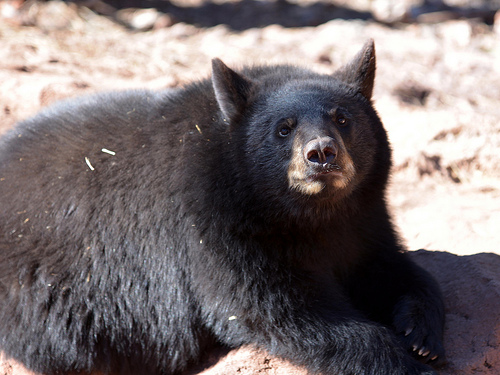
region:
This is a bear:
[6, 35, 451, 368]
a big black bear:
[38, 44, 453, 341]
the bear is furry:
[32, 48, 424, 314]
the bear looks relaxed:
[21, 57, 468, 350]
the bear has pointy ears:
[194, 31, 399, 225]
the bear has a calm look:
[269, 94, 364, 209]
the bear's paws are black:
[344, 287, 463, 373]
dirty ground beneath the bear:
[25, 11, 368, 61]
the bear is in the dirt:
[15, 94, 444, 363]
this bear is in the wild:
[172, 24, 462, 371]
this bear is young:
[29, 42, 475, 374]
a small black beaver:
[3, 40, 454, 372]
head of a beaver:
[197, 31, 392, 216]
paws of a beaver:
[346, 295, 471, 370]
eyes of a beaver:
[265, 95, 350, 140]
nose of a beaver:
[290, 130, 355, 175]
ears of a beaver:
[190, 25, 390, 120]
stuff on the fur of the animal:
[78, 133, 119, 168]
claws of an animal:
[405, 327, 445, 369]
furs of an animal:
[97, 183, 194, 248]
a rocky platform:
[205, 240, 495, 367]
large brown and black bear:
[5, 39, 453, 354]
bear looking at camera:
[206, 36, 394, 228]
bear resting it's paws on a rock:
[260, 240, 479, 366]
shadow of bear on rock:
[382, 226, 495, 356]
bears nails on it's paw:
[395, 317, 444, 367]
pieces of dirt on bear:
[77, 140, 122, 183]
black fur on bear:
[80, 207, 167, 330]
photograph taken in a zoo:
[13, 48, 475, 363]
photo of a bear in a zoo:
[18, 53, 447, 357]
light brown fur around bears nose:
[263, 110, 375, 202]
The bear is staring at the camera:
[208, 48, 430, 203]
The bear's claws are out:
[393, 315, 455, 362]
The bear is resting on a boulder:
[196, 243, 485, 373]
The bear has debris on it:
[51, 117, 214, 177]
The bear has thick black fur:
[29, 184, 240, 306]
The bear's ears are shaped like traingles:
[198, 42, 415, 102]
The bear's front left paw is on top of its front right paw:
[316, 269, 457, 372]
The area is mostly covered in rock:
[43, 8, 483, 56]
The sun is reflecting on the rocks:
[408, 34, 490, 234]